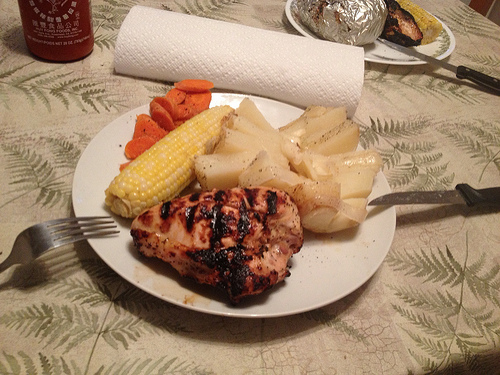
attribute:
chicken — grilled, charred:
[156, 196, 293, 279]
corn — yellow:
[121, 113, 196, 197]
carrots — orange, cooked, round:
[120, 84, 178, 158]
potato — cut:
[275, 125, 340, 208]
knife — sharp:
[376, 188, 499, 210]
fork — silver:
[49, 205, 126, 259]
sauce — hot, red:
[22, 3, 109, 63]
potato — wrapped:
[315, 14, 366, 33]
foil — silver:
[355, 11, 366, 34]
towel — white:
[160, 34, 305, 82]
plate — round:
[91, 156, 110, 192]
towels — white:
[120, 25, 353, 100]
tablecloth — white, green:
[11, 79, 55, 217]